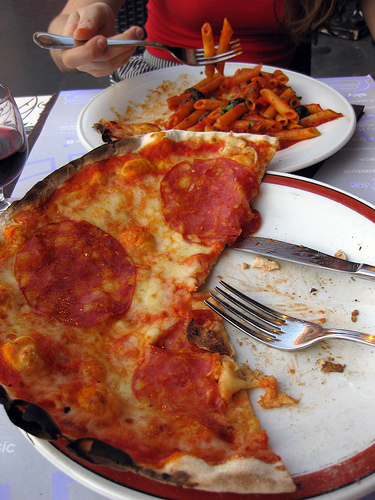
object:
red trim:
[257, 169, 375, 224]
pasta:
[200, 17, 234, 77]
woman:
[46, 0, 375, 91]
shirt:
[145, 1, 291, 62]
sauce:
[150, 292, 158, 299]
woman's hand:
[47, 0, 141, 77]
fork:
[33, 31, 243, 67]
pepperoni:
[160, 158, 255, 245]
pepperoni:
[131, 321, 225, 425]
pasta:
[167, 63, 342, 149]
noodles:
[165, 66, 342, 151]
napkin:
[349, 101, 366, 125]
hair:
[290, 0, 355, 18]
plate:
[0, 168, 375, 500]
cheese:
[251, 256, 279, 272]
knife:
[227, 234, 375, 281]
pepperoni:
[13, 218, 137, 330]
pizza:
[0, 133, 300, 498]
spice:
[225, 98, 240, 111]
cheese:
[135, 282, 168, 320]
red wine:
[0, 127, 29, 199]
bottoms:
[109, 48, 184, 88]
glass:
[0, 85, 29, 213]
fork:
[203, 279, 375, 353]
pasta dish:
[75, 59, 357, 178]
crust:
[8, 136, 141, 209]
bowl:
[77, 59, 356, 184]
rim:
[288, 447, 375, 500]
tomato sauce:
[154, 87, 166, 108]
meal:
[0, 19, 344, 500]